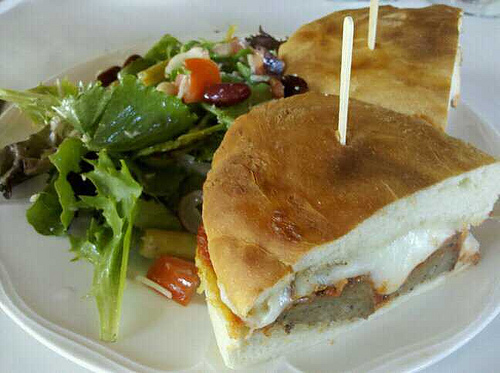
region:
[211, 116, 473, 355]
A Tasty Pizza Sandwich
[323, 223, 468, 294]
Melted Mozzarella Cheese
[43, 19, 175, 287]
Green Leafy Side Salad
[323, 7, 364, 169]
A Pick holding the sandwhich together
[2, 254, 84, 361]
A white Ceramic Plate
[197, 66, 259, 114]
Some Sort of Bean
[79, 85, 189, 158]
Some type of Lettuce Leaf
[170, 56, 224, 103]
A possible red Tomato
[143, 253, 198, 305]
A Possible Red Pepper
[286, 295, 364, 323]
Piece of Meat on the Sandwich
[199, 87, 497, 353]
meatball sandwich on plate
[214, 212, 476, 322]
mozzarella cheese melting over meatballs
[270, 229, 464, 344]
two halves of meatballs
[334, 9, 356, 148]
toothpick stuck into sandwich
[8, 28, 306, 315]
side salad on plate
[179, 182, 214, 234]
green olive in salad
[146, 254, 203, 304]
diced tomato on salad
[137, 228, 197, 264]
crouton on salad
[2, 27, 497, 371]
white plate on tablecloth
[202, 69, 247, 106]
black olive on salad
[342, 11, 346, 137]
Wooden stick sticking in bun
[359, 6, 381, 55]
Wooden stick sticking in bun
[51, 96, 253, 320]
Green lettuce leaves on plate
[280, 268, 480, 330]
Gray meat on burger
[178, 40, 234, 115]
Red tomato piece in salad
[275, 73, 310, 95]
Black olives in salad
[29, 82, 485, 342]
White round plate on table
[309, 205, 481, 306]
White melted cheese on burger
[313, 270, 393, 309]
red ketchup in burger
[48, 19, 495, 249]
Burger with salad on plate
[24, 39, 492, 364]
the plate is white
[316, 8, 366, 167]
wooden stick in sandwich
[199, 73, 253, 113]
bean in a salad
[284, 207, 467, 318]
a sauce on the sandwich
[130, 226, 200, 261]
a pepperoncini in the plate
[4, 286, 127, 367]
edge of a white plate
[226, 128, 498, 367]
cut bread of a sandwich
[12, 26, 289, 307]
salad sitting beside plate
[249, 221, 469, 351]
dark meat on a sandwich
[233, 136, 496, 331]
white bread with brown crust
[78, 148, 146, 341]
leaf of lettuce